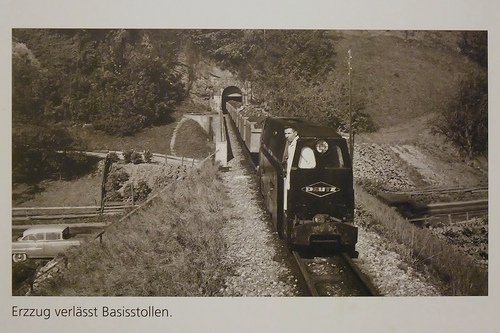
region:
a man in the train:
[267, 112, 312, 246]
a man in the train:
[268, 116, 315, 253]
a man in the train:
[266, 108, 348, 260]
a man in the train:
[249, 105, 339, 265]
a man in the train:
[262, 113, 326, 265]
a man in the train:
[257, 112, 364, 306]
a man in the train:
[261, 112, 340, 254]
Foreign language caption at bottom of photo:
[6, 300, 178, 324]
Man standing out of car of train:
[278, 123, 317, 220]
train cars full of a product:
[224, 94, 271, 151]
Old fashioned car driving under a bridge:
[16, 213, 96, 262]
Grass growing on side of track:
[46, 148, 226, 294]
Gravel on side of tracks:
[222, 159, 298, 297]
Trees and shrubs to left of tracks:
[18, 27, 186, 136]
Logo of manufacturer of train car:
[291, 173, 345, 201]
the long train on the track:
[220, 96, 357, 256]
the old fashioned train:
[225, 99, 357, 256]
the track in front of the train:
[289, 248, 381, 299]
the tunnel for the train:
[221, 85, 243, 115]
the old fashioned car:
[13, 226, 86, 263]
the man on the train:
[282, 123, 316, 211]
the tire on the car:
[13, 252, 27, 264]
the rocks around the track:
[214, 98, 441, 299]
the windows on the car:
[22, 232, 60, 242]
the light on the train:
[315, 140, 329, 154]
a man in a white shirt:
[276, 125, 319, 222]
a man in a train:
[256, 112, 358, 255]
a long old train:
[221, 91, 360, 255]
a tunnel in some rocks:
[211, 73, 255, 118]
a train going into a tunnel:
[216, 81, 362, 260]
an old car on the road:
[11, 221, 88, 266]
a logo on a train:
[296, 179, 342, 201]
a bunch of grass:
[18, 158, 234, 297]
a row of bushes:
[105, 148, 159, 167]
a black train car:
[256, 112, 360, 257]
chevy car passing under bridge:
[12, 223, 93, 261]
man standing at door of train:
[275, 127, 317, 239]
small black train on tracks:
[262, 115, 362, 252]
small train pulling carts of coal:
[226, 95, 364, 247]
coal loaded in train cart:
[248, 117, 268, 133]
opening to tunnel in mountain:
[217, 81, 247, 113]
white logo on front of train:
[298, 179, 345, 198]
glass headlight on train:
[314, 138, 331, 153]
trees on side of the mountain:
[77, 48, 197, 134]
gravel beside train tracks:
[232, 156, 257, 218]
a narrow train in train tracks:
[211, 73, 370, 283]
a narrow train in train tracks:
[229, 86, 345, 287]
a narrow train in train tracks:
[246, 85, 363, 276]